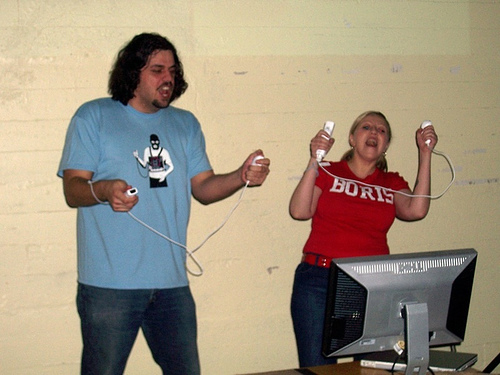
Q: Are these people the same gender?
A: No, they are both male and female.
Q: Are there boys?
A: No, there are no boys.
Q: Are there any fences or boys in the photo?
A: No, there are no boys or fences.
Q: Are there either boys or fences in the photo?
A: No, there are no boys or fences.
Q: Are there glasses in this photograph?
A: No, there are no glasses.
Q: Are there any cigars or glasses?
A: No, there are no glasses or cigars.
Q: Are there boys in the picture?
A: No, there are no boys.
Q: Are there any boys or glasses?
A: No, there are no boys or glasses.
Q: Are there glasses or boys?
A: No, there are no boys or glasses.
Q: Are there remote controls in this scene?
A: Yes, there is a remote control.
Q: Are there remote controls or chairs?
A: Yes, there is a remote control.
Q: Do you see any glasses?
A: No, there are no glasses.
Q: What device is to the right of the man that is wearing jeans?
A: The device is a remote control.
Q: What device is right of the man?
A: The device is a remote control.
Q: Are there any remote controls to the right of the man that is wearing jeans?
A: Yes, there is a remote control to the right of the man.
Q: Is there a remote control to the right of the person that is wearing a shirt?
A: Yes, there is a remote control to the right of the man.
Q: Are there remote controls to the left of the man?
A: No, the remote control is to the right of the man.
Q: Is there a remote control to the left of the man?
A: No, the remote control is to the right of the man.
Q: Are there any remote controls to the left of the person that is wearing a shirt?
A: No, the remote control is to the right of the man.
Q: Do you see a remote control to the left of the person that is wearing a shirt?
A: No, the remote control is to the right of the man.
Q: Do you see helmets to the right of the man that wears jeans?
A: No, there is a remote control to the right of the man.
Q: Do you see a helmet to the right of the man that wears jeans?
A: No, there is a remote control to the right of the man.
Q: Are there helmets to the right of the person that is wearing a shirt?
A: No, there is a remote control to the right of the man.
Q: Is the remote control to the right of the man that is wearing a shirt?
A: Yes, the remote control is to the right of the man.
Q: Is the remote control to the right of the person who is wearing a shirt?
A: Yes, the remote control is to the right of the man.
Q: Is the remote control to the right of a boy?
A: No, the remote control is to the right of the man.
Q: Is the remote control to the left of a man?
A: No, the remote control is to the right of a man.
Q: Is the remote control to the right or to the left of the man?
A: The remote control is to the right of the man.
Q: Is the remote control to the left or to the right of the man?
A: The remote control is to the right of the man.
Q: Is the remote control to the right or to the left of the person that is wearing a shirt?
A: The remote control is to the right of the man.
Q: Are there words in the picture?
A: Yes, there are words.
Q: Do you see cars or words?
A: Yes, there are words.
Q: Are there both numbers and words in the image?
A: No, there are words but no numbers.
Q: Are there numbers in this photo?
A: No, there are no numbers.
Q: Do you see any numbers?
A: No, there are no numbers.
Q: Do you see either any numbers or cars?
A: No, there are no numbers or cars.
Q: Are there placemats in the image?
A: No, there are no placemats.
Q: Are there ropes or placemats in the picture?
A: No, there are no placemats or ropes.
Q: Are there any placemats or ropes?
A: No, there are no placemats or ropes.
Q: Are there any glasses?
A: No, there are no glasses.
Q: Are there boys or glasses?
A: No, there are no glasses or boys.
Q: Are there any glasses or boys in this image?
A: No, there are no glasses or boys.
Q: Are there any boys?
A: No, there are no boys.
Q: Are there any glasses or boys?
A: No, there are no boys or glasses.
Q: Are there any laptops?
A: Yes, there is a laptop.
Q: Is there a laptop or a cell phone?
A: Yes, there is a laptop.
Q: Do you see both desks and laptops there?
A: Yes, there are both a laptop and a desk.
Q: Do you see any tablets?
A: No, there are no tablets.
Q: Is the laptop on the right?
A: Yes, the laptop is on the right of the image.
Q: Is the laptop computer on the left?
A: No, the laptop computer is on the right of the image.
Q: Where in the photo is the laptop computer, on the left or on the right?
A: The laptop computer is on the right of the image.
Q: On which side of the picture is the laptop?
A: The laptop is on the right of the image.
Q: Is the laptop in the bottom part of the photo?
A: Yes, the laptop is in the bottom of the image.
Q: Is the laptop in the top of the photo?
A: No, the laptop is in the bottom of the image.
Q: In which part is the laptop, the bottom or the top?
A: The laptop is in the bottom of the image.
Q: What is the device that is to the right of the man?
A: The device is a laptop.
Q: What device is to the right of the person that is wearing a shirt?
A: The device is a laptop.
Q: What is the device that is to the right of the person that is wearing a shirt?
A: The device is a laptop.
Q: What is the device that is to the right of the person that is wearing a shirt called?
A: The device is a laptop.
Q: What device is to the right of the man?
A: The device is a laptop.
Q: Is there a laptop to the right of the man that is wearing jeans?
A: Yes, there is a laptop to the right of the man.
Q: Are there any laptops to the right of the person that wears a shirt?
A: Yes, there is a laptop to the right of the man.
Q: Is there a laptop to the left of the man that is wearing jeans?
A: No, the laptop is to the right of the man.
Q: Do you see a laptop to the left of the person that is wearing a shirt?
A: No, the laptop is to the right of the man.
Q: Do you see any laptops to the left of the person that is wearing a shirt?
A: No, the laptop is to the right of the man.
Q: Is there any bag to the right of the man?
A: No, there is a laptop to the right of the man.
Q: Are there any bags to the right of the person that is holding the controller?
A: No, there is a laptop to the right of the man.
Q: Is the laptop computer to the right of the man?
A: Yes, the laptop computer is to the right of the man.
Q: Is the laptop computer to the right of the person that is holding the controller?
A: Yes, the laptop computer is to the right of the man.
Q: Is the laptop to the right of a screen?
A: No, the laptop is to the right of the man.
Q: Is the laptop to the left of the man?
A: No, the laptop is to the right of the man.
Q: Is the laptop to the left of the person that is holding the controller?
A: No, the laptop is to the right of the man.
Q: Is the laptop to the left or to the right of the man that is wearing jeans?
A: The laptop is to the right of the man.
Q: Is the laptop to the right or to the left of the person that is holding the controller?
A: The laptop is to the right of the man.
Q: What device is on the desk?
A: The device is a laptop.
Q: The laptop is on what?
A: The laptop is on the desk.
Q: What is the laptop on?
A: The laptop is on the desk.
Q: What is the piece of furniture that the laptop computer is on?
A: The piece of furniture is a desk.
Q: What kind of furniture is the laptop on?
A: The laptop computer is on the desk.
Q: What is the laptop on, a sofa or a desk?
A: The laptop is on a desk.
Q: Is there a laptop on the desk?
A: Yes, there is a laptop on the desk.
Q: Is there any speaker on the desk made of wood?
A: No, there is a laptop on the desk.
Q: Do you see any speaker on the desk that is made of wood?
A: No, there is a laptop on the desk.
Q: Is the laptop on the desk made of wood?
A: Yes, the laptop is on the desk.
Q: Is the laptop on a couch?
A: No, the laptop is on the desk.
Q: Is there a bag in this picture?
A: No, there are no bags.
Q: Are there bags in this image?
A: No, there are no bags.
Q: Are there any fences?
A: No, there are no fences.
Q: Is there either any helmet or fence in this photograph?
A: No, there are no fences or helmets.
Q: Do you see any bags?
A: No, there are no bags.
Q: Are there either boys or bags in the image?
A: No, there are no bags or boys.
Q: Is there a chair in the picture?
A: No, there are no chairs.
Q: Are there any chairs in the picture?
A: No, there are no chairs.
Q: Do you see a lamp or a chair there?
A: No, there are no chairs or lamps.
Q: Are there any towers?
A: No, there are no towers.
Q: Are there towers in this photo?
A: No, there are no towers.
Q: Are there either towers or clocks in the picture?
A: No, there are no towers or clocks.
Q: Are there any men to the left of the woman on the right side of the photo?
A: Yes, there is a man to the left of the woman.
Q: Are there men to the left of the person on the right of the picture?
A: Yes, there is a man to the left of the woman.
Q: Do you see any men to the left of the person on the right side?
A: Yes, there is a man to the left of the woman.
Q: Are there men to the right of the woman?
A: No, the man is to the left of the woman.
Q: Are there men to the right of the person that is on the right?
A: No, the man is to the left of the woman.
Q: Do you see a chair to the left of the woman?
A: No, there is a man to the left of the woman.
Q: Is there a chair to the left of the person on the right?
A: No, there is a man to the left of the woman.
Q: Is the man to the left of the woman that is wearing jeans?
A: Yes, the man is to the left of the woman.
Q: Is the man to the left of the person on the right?
A: Yes, the man is to the left of the woman.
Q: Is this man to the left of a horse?
A: No, the man is to the left of the woman.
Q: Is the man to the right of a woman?
A: No, the man is to the left of a woman.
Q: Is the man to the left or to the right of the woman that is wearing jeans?
A: The man is to the left of the woman.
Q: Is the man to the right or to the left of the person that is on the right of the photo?
A: The man is to the left of the woman.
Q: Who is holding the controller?
A: The man is holding the controller.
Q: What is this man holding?
A: The man is holding the controller.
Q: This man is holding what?
A: The man is holding the controller.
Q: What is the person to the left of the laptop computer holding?
A: The man is holding the controller.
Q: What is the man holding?
A: The man is holding the controller.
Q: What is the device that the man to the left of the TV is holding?
A: The device is a controller.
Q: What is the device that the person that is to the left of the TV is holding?
A: The device is a controller.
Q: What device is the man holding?
A: The man is holding the controller.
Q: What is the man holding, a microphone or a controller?
A: The man is holding a controller.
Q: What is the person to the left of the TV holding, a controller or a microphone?
A: The man is holding a controller.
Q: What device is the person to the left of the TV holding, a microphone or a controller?
A: The man is holding a controller.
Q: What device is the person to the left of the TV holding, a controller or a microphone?
A: The man is holding a controller.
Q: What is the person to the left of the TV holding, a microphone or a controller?
A: The man is holding a controller.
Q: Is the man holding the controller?
A: Yes, the man is holding the controller.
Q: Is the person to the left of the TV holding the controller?
A: Yes, the man is holding the controller.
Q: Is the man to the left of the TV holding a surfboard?
A: No, the man is holding the controller.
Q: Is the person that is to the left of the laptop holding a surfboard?
A: No, the man is holding the controller.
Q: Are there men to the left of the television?
A: Yes, there is a man to the left of the television.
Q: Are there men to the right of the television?
A: No, the man is to the left of the television.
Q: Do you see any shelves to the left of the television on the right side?
A: No, there is a man to the left of the television.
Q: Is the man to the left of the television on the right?
A: Yes, the man is to the left of the television.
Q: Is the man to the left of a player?
A: No, the man is to the left of the television.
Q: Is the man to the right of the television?
A: No, the man is to the left of the television.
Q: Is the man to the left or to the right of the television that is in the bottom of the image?
A: The man is to the left of the TV.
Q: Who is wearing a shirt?
A: The man is wearing a shirt.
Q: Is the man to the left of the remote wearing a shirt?
A: Yes, the man is wearing a shirt.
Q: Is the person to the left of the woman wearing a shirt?
A: Yes, the man is wearing a shirt.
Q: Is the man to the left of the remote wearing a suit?
A: No, the man is wearing a shirt.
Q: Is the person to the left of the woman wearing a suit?
A: No, the man is wearing a shirt.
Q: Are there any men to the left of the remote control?
A: Yes, there is a man to the left of the remote control.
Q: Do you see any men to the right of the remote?
A: No, the man is to the left of the remote.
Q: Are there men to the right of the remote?
A: No, the man is to the left of the remote.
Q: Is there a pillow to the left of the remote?
A: No, there is a man to the left of the remote.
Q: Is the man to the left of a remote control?
A: Yes, the man is to the left of a remote control.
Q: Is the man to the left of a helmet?
A: No, the man is to the left of a remote control.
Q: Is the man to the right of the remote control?
A: No, the man is to the left of the remote control.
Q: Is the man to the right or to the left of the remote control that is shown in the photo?
A: The man is to the left of the remote control.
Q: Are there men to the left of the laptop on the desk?
A: Yes, there is a man to the left of the laptop computer.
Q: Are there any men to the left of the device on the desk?
A: Yes, there is a man to the left of the laptop computer.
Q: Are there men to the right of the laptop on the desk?
A: No, the man is to the left of the laptop computer.